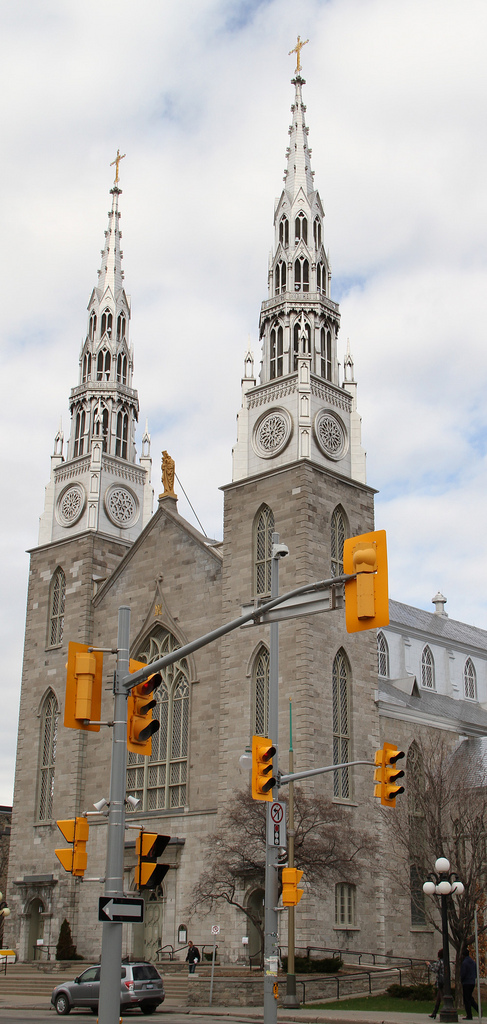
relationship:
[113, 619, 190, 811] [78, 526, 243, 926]
window on building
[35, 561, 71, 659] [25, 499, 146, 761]
window on building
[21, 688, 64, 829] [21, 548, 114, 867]
window on building